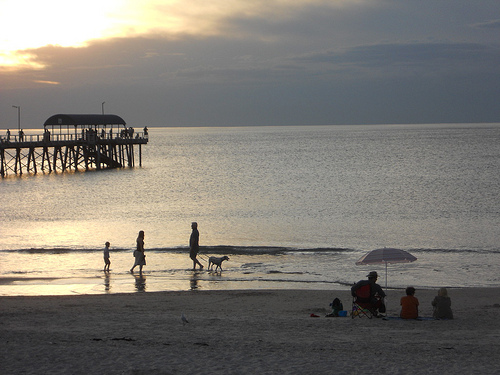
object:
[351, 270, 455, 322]
people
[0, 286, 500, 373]
beach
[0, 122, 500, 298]
ocean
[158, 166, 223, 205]
water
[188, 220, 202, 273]
man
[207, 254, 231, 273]
dog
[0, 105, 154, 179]
pier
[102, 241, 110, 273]
small child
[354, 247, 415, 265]
umbrella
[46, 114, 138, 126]
roof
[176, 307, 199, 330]
seagull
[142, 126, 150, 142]
man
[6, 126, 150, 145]
people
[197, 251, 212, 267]
leash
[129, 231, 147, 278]
woman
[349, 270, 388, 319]
man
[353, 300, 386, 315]
chair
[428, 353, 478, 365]
sand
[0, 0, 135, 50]
sun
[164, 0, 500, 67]
clouds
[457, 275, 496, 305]
shore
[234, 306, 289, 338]
on beach